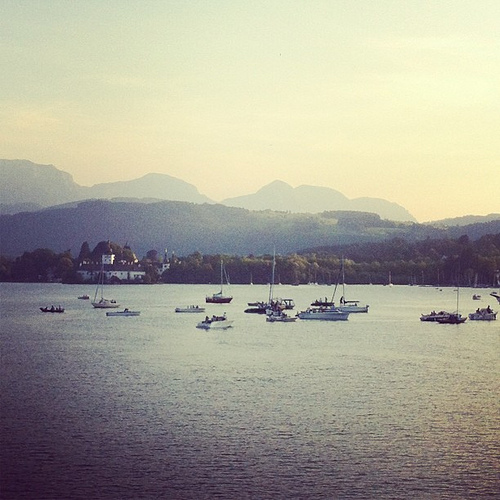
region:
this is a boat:
[36, 296, 75, 326]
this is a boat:
[196, 309, 239, 340]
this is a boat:
[171, 295, 206, 316]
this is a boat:
[296, 300, 349, 331]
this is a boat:
[423, 302, 464, 341]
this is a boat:
[463, 296, 498, 352]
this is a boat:
[203, 250, 238, 308]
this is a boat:
[88, 285, 126, 305]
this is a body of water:
[29, 330, 192, 461]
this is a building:
[77, 216, 164, 296]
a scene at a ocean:
[14, 34, 499, 489]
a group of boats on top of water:
[29, 261, 498, 335]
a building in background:
[43, 223, 200, 299]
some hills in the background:
[32, 152, 487, 288]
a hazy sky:
[13, 8, 488, 216]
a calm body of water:
[8, 270, 499, 488]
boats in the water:
[157, 267, 387, 351]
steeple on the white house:
[97, 240, 114, 266]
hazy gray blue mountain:
[132, 171, 195, 200]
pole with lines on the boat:
[217, 257, 226, 297]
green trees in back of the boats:
[296, 255, 370, 275]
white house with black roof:
[70, 245, 151, 283]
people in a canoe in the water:
[35, 305, 69, 317]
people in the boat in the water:
[417, 306, 452, 325]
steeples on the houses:
[162, 243, 169, 259]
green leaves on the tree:
[456, 256, 471, 271]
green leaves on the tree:
[417, 261, 457, 281]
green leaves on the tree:
[367, 245, 398, 275]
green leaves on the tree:
[347, 253, 365, 267]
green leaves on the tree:
[290, 261, 306, 281]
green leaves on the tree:
[252, 252, 272, 279]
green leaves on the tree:
[187, 254, 214, 274]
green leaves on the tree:
[242, 224, 264, 241]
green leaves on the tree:
[185, 206, 200, 221]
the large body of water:
[0, 281, 499, 498]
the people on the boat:
[39, 303, 64, 313]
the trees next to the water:
[1, 232, 498, 499]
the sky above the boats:
[0, 0, 499, 499]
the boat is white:
[197, 310, 233, 329]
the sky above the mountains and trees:
[1, 1, 498, 286]